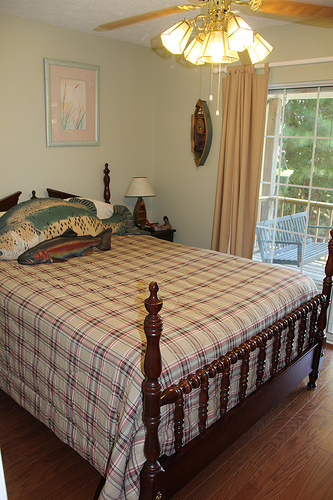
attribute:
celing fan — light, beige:
[96, 1, 332, 101]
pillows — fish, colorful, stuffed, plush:
[0, 196, 137, 263]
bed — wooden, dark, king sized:
[2, 166, 332, 490]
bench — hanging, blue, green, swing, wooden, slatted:
[253, 202, 333, 262]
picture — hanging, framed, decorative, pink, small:
[45, 65, 98, 147]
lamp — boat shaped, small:
[122, 176, 160, 225]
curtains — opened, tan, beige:
[206, 60, 260, 260]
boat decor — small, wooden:
[187, 100, 216, 169]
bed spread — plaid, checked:
[4, 222, 321, 489]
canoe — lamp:
[133, 198, 149, 230]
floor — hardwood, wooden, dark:
[6, 351, 332, 500]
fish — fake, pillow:
[16, 220, 113, 270]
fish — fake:
[197, 109, 202, 142]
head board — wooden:
[2, 158, 124, 217]